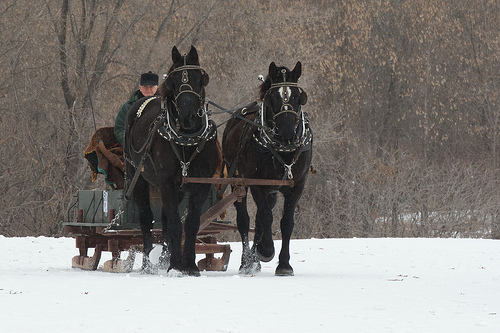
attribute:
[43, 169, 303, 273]
sleigh — green, brown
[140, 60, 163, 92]
hat — green, black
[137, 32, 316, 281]
horses — Two black   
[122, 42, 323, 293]
horses — Two black   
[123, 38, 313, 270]
horses — two black 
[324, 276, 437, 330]
snow — small patch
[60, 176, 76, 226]
trunks — black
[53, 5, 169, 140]
tree — bare 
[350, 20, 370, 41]
leaves — yellow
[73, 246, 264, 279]
vehicle — bottom 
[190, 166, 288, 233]
bars — brown 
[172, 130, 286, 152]
neck — horse's 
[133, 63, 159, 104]
head — man's 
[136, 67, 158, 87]
cap — black 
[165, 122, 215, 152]
neck — horse's  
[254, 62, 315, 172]
head — horses 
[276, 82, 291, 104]
spot — white 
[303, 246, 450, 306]
snow — white 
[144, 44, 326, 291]
horses — black 